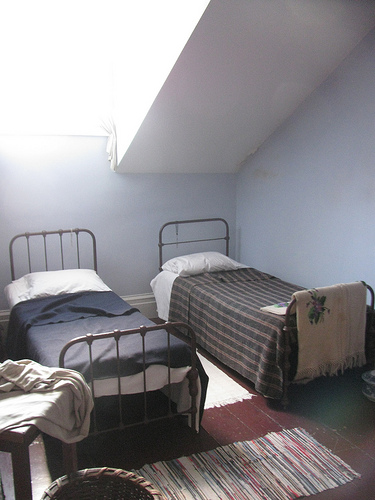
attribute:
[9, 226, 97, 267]
frame — black, metal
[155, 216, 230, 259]
frame — black, metal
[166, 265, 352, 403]
bed spread — black, white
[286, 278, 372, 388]
blanket — white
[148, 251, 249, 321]
sheets — white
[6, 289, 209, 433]
blanket — black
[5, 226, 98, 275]
headboard — iron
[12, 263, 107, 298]
pillow — white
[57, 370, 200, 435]
frame — metal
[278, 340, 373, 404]
frame — metal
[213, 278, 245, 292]
part bed — back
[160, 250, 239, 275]
pillow — white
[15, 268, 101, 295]
pillow — white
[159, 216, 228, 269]
frame — black, metal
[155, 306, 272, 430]
rug — white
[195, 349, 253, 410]
rug — white